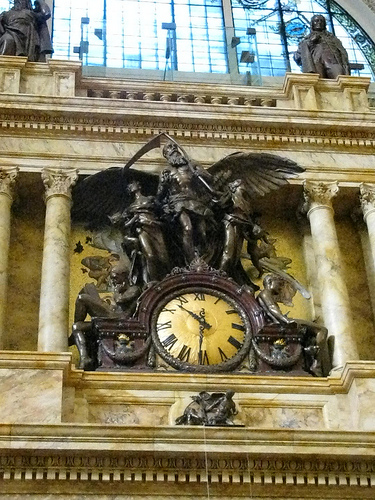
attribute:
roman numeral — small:
[217, 345, 231, 364]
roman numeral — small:
[171, 341, 194, 364]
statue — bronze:
[106, 180, 177, 286]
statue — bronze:
[153, 137, 221, 269]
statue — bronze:
[217, 176, 271, 277]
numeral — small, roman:
[192, 288, 206, 302]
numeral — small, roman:
[193, 349, 212, 365]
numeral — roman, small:
[159, 332, 180, 349]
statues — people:
[111, 139, 249, 271]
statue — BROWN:
[72, 139, 305, 263]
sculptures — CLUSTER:
[66, 143, 327, 376]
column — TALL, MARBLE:
[34, 167, 81, 349]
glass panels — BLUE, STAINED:
[52, 6, 358, 77]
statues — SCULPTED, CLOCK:
[70, 124, 327, 364]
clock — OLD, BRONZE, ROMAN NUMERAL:
[143, 276, 260, 372]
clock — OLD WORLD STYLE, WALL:
[141, 282, 253, 367]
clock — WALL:
[148, 285, 252, 371]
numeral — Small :
[216, 297, 222, 306]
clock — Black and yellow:
[157, 290, 247, 368]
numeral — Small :
[224, 307, 236, 314]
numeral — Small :
[232, 324, 245, 332]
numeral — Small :
[226, 333, 242, 350]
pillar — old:
[18, 157, 82, 264]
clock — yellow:
[151, 268, 269, 375]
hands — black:
[167, 296, 224, 358]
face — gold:
[177, 278, 241, 367]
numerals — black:
[158, 289, 250, 366]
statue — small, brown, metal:
[173, 391, 239, 428]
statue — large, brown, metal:
[96, 163, 272, 276]